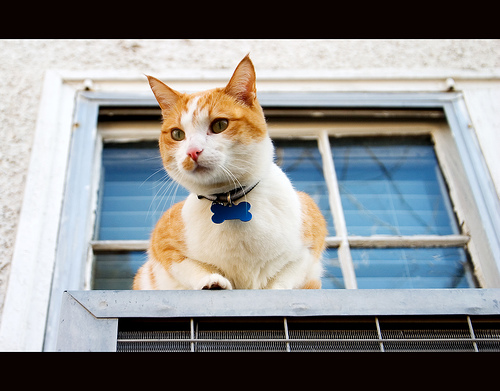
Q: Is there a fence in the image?
A: No, there are no fences.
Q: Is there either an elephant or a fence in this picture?
A: No, there are no fences or elephants.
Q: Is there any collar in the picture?
A: Yes, there is a collar.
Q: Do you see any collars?
A: Yes, there is a collar.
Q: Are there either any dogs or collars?
A: Yes, there is a collar.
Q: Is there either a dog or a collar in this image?
A: Yes, there is a collar.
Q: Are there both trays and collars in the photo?
A: No, there is a collar but no trays.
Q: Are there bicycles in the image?
A: No, there are no bicycles.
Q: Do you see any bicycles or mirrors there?
A: No, there are no bicycles or mirrors.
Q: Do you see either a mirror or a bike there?
A: No, there are no bikes or mirrors.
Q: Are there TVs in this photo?
A: No, there are no tvs.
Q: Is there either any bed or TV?
A: No, there are no televisions or beds.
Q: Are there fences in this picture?
A: No, there are no fences.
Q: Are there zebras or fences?
A: No, there are no fences or zebras.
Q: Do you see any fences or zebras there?
A: No, there are no fences or zebras.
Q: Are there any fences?
A: No, there are no fences.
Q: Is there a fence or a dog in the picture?
A: No, there are no fences or dogs.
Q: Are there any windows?
A: Yes, there is a window.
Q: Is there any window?
A: Yes, there is a window.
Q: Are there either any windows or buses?
A: Yes, there is a window.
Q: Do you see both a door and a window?
A: No, there is a window but no doors.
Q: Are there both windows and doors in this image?
A: No, there is a window but no doors.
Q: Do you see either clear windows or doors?
A: Yes, there is a clear window.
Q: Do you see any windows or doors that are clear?
A: Yes, the window is clear.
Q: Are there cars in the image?
A: No, there are no cars.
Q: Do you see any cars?
A: No, there are no cars.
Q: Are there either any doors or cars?
A: No, there are no cars or doors.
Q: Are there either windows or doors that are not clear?
A: No, there is a window but it is clear.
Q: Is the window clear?
A: Yes, the window is clear.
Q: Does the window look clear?
A: Yes, the window is clear.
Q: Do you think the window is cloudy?
A: No, the window is clear.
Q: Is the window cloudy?
A: No, the window is clear.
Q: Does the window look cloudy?
A: No, the window is clear.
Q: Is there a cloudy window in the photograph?
A: No, there is a window but it is clear.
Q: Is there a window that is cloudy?
A: No, there is a window but it is clear.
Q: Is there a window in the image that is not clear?
A: No, there is a window but it is clear.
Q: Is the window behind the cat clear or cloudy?
A: The window is clear.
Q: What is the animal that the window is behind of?
A: The animal is a cat.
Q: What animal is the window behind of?
A: The window is behind the cat.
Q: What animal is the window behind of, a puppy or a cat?
A: The window is behind a cat.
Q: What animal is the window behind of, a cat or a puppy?
A: The window is behind a cat.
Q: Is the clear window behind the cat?
A: Yes, the window is behind the cat.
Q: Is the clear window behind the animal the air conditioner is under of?
A: Yes, the window is behind the cat.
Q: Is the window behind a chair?
A: No, the window is behind the cat.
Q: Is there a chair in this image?
A: No, there are no chairs.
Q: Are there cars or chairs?
A: No, there are no chairs or cars.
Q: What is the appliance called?
A: The appliance is an air conditioner.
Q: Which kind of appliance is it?
A: The appliance is an air conditioner.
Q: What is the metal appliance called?
A: The appliance is an air conditioner.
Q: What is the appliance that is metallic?
A: The appliance is an air conditioner.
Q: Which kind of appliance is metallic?
A: The appliance is an air conditioner.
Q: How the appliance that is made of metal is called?
A: The appliance is an air conditioner.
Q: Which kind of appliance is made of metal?
A: The appliance is an air conditioner.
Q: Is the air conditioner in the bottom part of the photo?
A: Yes, the air conditioner is in the bottom of the image.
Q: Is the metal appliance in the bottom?
A: Yes, the air conditioner is in the bottom of the image.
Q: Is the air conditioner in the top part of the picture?
A: No, the air conditioner is in the bottom of the image.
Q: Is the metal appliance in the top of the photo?
A: No, the air conditioner is in the bottom of the image.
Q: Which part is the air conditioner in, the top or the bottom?
A: The air conditioner is in the bottom of the image.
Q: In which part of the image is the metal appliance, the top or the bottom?
A: The air conditioner is in the bottom of the image.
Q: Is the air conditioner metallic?
A: Yes, the air conditioner is metallic.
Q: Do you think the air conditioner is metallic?
A: Yes, the air conditioner is metallic.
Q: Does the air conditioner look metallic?
A: Yes, the air conditioner is metallic.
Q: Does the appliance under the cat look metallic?
A: Yes, the air conditioner is metallic.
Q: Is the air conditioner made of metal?
A: Yes, the air conditioner is made of metal.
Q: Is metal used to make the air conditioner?
A: Yes, the air conditioner is made of metal.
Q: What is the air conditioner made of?
A: The air conditioner is made of metal.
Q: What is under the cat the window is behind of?
A: The air conditioner is under the cat.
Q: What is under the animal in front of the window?
A: The air conditioner is under the cat.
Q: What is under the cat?
A: The air conditioner is under the cat.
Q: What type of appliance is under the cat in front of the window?
A: The appliance is an air conditioner.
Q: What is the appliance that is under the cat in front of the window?
A: The appliance is an air conditioner.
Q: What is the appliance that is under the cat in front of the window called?
A: The appliance is an air conditioner.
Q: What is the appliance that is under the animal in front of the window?
A: The appliance is an air conditioner.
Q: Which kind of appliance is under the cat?
A: The appliance is an air conditioner.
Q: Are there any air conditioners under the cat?
A: Yes, there is an air conditioner under the cat.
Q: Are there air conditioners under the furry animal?
A: Yes, there is an air conditioner under the cat.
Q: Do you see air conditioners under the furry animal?
A: Yes, there is an air conditioner under the cat.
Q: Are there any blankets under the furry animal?
A: No, there is an air conditioner under the cat.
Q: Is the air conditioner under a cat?
A: Yes, the air conditioner is under a cat.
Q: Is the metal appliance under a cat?
A: Yes, the air conditioner is under a cat.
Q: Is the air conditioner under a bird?
A: No, the air conditioner is under a cat.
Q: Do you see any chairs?
A: No, there are no chairs.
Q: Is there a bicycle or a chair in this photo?
A: No, there are no chairs or bicycles.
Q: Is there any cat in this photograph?
A: Yes, there is a cat.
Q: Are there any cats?
A: Yes, there is a cat.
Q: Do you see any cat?
A: Yes, there is a cat.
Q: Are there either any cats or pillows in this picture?
A: Yes, there is a cat.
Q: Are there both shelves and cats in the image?
A: No, there is a cat but no shelves.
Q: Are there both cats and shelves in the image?
A: No, there is a cat but no shelves.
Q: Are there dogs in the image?
A: No, there are no dogs.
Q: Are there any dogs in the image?
A: No, there are no dogs.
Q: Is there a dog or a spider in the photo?
A: No, there are no dogs or spiders.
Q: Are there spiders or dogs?
A: No, there are no dogs or spiders.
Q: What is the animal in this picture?
A: The animal is a cat.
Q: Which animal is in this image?
A: The animal is a cat.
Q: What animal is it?
A: The animal is a cat.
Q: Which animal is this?
A: This is a cat.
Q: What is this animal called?
A: This is a cat.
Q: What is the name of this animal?
A: This is a cat.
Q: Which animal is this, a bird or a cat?
A: This is a cat.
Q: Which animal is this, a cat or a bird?
A: This is a cat.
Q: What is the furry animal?
A: The animal is a cat.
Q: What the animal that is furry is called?
A: The animal is a cat.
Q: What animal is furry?
A: The animal is a cat.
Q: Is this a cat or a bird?
A: This is a cat.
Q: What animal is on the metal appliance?
A: The cat is on the air conditioner.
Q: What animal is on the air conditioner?
A: The cat is on the air conditioner.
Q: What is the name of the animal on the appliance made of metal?
A: The animal is a cat.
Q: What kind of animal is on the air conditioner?
A: The animal is a cat.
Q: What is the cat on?
A: The cat is on the air conditioner.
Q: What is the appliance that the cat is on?
A: The appliance is an air conditioner.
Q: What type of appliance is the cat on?
A: The cat is on the air conditioner.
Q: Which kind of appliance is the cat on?
A: The cat is on the air conditioner.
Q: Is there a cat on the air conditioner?
A: Yes, there is a cat on the air conditioner.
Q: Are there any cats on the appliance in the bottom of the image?
A: Yes, there is a cat on the air conditioner.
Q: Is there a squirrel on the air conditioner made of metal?
A: No, there is a cat on the air conditioner.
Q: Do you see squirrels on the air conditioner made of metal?
A: No, there is a cat on the air conditioner.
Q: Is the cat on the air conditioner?
A: Yes, the cat is on the air conditioner.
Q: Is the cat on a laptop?
A: No, the cat is on the air conditioner.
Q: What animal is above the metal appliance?
A: The animal is a cat.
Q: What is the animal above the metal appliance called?
A: The animal is a cat.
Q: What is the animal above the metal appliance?
A: The animal is a cat.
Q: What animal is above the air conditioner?
A: The animal is a cat.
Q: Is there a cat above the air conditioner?
A: Yes, there is a cat above the air conditioner.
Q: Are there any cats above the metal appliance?
A: Yes, there is a cat above the air conditioner.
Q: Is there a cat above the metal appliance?
A: Yes, there is a cat above the air conditioner.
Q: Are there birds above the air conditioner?
A: No, there is a cat above the air conditioner.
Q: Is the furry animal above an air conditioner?
A: Yes, the cat is above an air conditioner.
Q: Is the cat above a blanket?
A: No, the cat is above an air conditioner.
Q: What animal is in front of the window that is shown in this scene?
A: The cat is in front of the window.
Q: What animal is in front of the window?
A: The cat is in front of the window.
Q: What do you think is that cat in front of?
A: The cat is in front of the window.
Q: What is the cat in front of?
A: The cat is in front of the window.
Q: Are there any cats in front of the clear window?
A: Yes, there is a cat in front of the window.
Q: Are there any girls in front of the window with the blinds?
A: No, there is a cat in front of the window.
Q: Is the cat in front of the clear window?
A: Yes, the cat is in front of the window.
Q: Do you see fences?
A: No, there are no fences.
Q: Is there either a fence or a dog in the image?
A: No, there are no fences or dogs.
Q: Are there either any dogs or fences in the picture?
A: No, there are no fences or dogs.